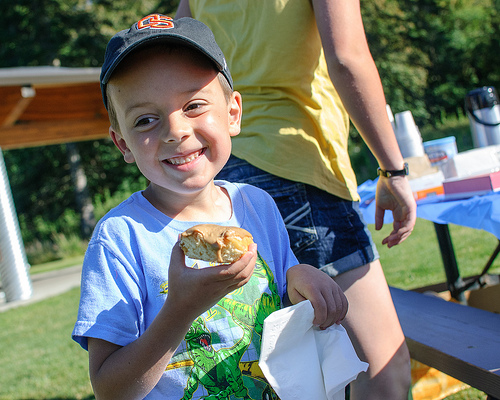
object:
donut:
[180, 224, 254, 263]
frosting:
[237, 237, 241, 240]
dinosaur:
[182, 320, 241, 396]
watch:
[379, 163, 409, 177]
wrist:
[378, 167, 409, 181]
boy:
[72, 15, 347, 399]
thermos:
[461, 86, 499, 147]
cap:
[99, 14, 234, 106]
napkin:
[256, 299, 372, 398]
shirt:
[70, 180, 301, 400]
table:
[341, 168, 500, 308]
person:
[177, 0, 413, 398]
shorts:
[213, 148, 380, 277]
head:
[102, 12, 242, 192]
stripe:
[284, 202, 310, 221]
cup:
[392, 109, 422, 158]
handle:
[471, 112, 500, 128]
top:
[188, 1, 363, 200]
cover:
[353, 171, 499, 235]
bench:
[389, 285, 498, 399]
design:
[162, 252, 282, 399]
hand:
[285, 264, 350, 329]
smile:
[160, 147, 207, 169]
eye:
[183, 99, 209, 114]